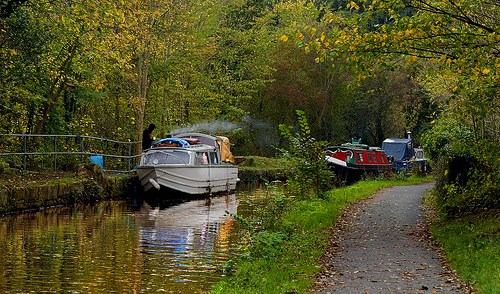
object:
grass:
[419, 178, 497, 271]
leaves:
[173, 34, 278, 77]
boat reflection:
[139, 190, 241, 257]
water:
[0, 181, 283, 294]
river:
[0, 177, 285, 292]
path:
[317, 171, 482, 292]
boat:
[325, 137, 394, 180]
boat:
[382, 137, 428, 175]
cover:
[382, 138, 412, 162]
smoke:
[164, 114, 256, 139]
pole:
[54, 136, 57, 172]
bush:
[264, 193, 330, 239]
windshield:
[143, 151, 189, 164]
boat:
[136, 133, 241, 197]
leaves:
[338, 220, 349, 230]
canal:
[4, 192, 281, 291]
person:
[142, 123, 156, 152]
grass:
[209, 178, 403, 291]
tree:
[1, 0, 134, 170]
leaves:
[417, 226, 455, 278]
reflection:
[28, 211, 114, 249]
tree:
[173, 0, 288, 122]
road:
[310, 175, 463, 291]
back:
[215, 140, 244, 179]